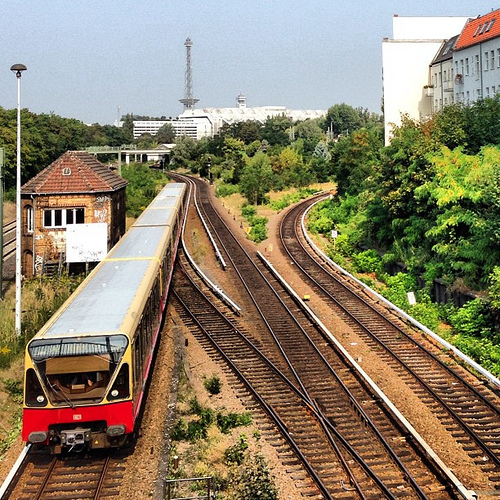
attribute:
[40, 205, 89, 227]
white pane — window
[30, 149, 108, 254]
building — old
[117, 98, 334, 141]
building — white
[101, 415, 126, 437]
bumper — black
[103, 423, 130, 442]
bumper — black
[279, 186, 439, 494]
railing — white, safety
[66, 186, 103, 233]
window — glass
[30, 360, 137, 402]
window — glass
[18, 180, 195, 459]
train — red, yellow, silver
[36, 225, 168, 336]
train top — grey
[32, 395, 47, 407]
headlight — off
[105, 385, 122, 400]
headlight — off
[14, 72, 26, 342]
lightpole — white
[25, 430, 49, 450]
bumper — car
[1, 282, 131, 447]
train — red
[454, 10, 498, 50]
roof — bright orange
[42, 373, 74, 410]
wiper — windshield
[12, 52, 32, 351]
pole — tall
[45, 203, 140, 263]
sign — white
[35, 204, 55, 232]
window — glass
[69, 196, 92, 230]
window — glass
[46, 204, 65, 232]
window — glass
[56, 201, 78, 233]
window — glass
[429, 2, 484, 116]
building — old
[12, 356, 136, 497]
tracks — railroad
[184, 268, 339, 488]
tracks — railroad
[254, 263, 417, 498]
tracks — railroad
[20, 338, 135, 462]
front — yellow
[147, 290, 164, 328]
window — glass